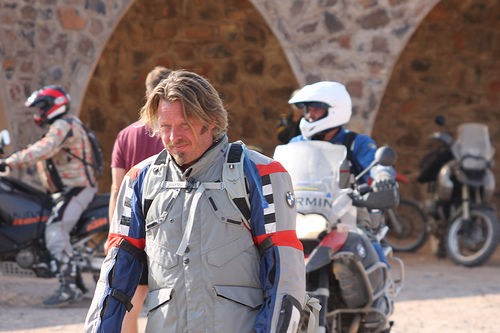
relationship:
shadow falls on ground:
[388, 246, 499, 306] [0, 240, 499, 330]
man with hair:
[15, 87, 102, 313] [165, 79, 220, 129]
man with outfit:
[15, 87, 102, 313] [29, 121, 91, 295]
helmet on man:
[22, 82, 87, 130] [2, 82, 105, 313]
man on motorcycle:
[286, 80, 396, 332] [301, 206, 414, 306]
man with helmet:
[286, 80, 396, 332] [285, 79, 351, 139]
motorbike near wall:
[415, 114, 497, 267] [80, 3, 307, 192]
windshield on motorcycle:
[272, 139, 347, 197] [270, 139, 405, 332]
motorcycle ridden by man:
[270, 139, 405, 332] [286, 79, 400, 330]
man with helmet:
[286, 79, 400, 330] [285, 79, 351, 139]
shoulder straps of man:
[140, 139, 250, 235] [86, 62, 316, 329]